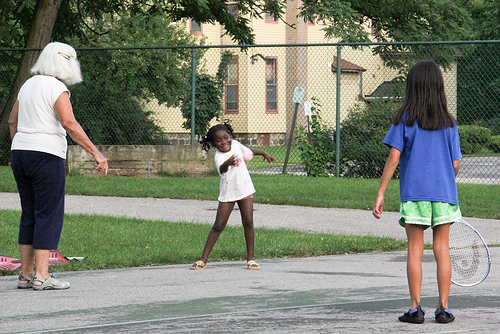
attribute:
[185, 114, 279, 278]
girl — playing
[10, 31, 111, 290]
woman — old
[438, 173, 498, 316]
racket — held, here, purple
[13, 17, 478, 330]
people — here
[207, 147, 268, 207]
shirt — white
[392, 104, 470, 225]
shirt — blue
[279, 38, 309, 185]
post — bent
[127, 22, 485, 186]
fence — here, chain, chain link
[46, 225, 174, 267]
grass — green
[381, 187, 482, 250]
shorts — green, gree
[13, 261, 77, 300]
shoes — grey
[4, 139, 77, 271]
poants — black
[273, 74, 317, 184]
sign — crooked, white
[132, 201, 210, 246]
sidewalk — grey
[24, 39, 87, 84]
hair — white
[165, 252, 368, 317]
asphault — grey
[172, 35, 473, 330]
children — playing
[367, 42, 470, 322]
girl — little